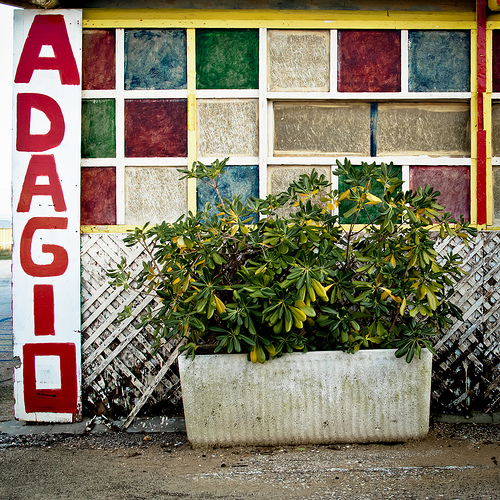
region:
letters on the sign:
[14, 15, 106, 361]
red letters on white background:
[17, 233, 87, 398]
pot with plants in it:
[161, 332, 442, 442]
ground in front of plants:
[230, 451, 301, 492]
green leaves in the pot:
[179, 250, 374, 373]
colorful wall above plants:
[110, 38, 301, 160]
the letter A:
[16, 11, 89, 91]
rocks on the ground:
[86, 420, 137, 450]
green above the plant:
[193, 28, 260, 90]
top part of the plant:
[329, 153, 374, 188]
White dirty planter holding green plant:
[177, 349, 438, 443]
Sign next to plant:
[10, 3, 82, 423]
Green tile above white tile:
[193, 27, 257, 89]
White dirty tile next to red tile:
[267, 25, 335, 95]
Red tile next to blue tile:
[335, 27, 401, 93]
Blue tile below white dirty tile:
[195, 162, 259, 222]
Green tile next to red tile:
[82, 95, 119, 160]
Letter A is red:
[16, 12, 81, 84]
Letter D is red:
[15, 87, 67, 151]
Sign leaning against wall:
[7, 9, 93, 424]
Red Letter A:
[15, 8, 81, 88]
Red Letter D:
[12, 86, 77, 151]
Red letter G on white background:
[15, 210, 80, 275]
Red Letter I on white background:
[20, 280, 56, 336]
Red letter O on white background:
[15, 335, 80, 415]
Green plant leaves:
[170, 216, 400, 326]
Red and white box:
[325, 20, 410, 105]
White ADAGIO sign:
[10, 5, 90, 420]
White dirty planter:
[160, 325, 460, 460]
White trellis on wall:
[90, 255, 158, 390]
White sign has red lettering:
[10, 2, 96, 429]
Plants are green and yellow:
[123, 165, 461, 352]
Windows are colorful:
[84, 24, 474, 241]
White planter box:
[175, 344, 460, 458]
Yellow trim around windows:
[83, 4, 475, 32]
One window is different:
[244, 78, 487, 174]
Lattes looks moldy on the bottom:
[88, 336, 497, 436]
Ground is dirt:
[11, 423, 491, 498]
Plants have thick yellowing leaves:
[250, 330, 277, 365]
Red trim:
[466, 2, 497, 236]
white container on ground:
[172, 347, 449, 468]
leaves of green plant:
[217, 241, 355, 331]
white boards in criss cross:
[87, 306, 132, 386]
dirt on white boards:
[89, 376, 153, 414]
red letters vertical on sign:
[8, 10, 78, 417]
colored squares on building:
[110, 20, 194, 229]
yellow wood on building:
[170, 12, 360, 32]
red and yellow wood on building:
[466, 40, 494, 222]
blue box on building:
[395, 20, 476, 104]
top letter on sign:
[2, 7, 79, 93]